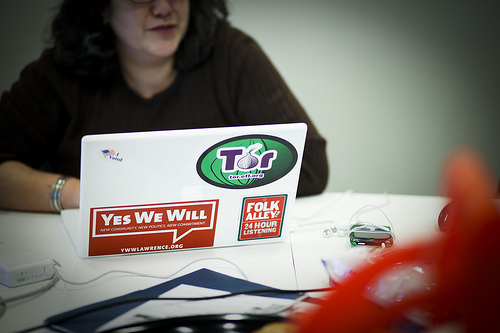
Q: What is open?
A: Laptop.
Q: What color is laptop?
A: White.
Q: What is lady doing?
A: Working.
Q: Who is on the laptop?
A: Lady.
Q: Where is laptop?
A: Table.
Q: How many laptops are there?
A: One.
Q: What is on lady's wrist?
A: Bracelet.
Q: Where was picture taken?
A: In an office.